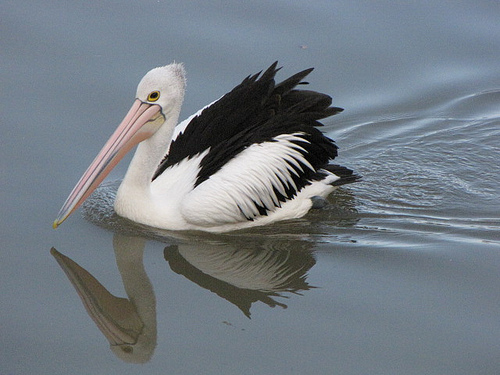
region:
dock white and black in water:
[30, 48, 370, 269]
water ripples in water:
[372, 126, 459, 198]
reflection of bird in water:
[45, 212, 330, 372]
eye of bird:
[143, 90, 162, 105]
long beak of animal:
[38, 98, 165, 230]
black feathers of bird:
[248, 56, 348, 115]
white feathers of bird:
[235, 163, 278, 203]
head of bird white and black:
[93, 53, 207, 177]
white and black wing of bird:
[180, 108, 331, 237]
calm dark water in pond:
[40, 33, 87, 83]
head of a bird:
[48, 50, 190, 255]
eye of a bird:
[142, 80, 170, 111]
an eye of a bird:
[134, 87, 170, 115]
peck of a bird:
[51, 99, 142, 219]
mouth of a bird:
[45, 107, 157, 232]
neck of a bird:
[133, 127, 170, 187]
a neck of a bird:
[112, 148, 179, 193]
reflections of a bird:
[58, 236, 308, 361]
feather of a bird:
[230, 30, 331, 140]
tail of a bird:
[280, 65, 359, 141]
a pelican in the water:
[20, 30, 372, 277]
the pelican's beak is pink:
[25, 90, 182, 235]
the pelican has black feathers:
[183, 65, 324, 152]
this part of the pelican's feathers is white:
[130, 153, 295, 232]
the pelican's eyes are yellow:
[137, 81, 163, 108]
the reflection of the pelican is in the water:
[25, 228, 312, 358]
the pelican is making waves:
[335, 120, 492, 264]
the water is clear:
[33, 244, 361, 371]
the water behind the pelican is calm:
[5, 6, 416, 109]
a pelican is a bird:
[36, 31, 369, 266]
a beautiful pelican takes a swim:
[32, 48, 382, 247]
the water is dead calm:
[3, 23, 490, 348]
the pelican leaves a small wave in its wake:
[43, 52, 497, 266]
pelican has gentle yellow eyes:
[143, 85, 164, 105]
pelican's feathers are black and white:
[45, 48, 369, 243]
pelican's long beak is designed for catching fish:
[41, 55, 191, 232]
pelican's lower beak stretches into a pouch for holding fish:
[47, 55, 195, 240]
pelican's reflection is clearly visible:
[36, 194, 343, 369]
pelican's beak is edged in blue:
[41, 88, 176, 238]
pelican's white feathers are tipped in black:
[174, 121, 346, 233]